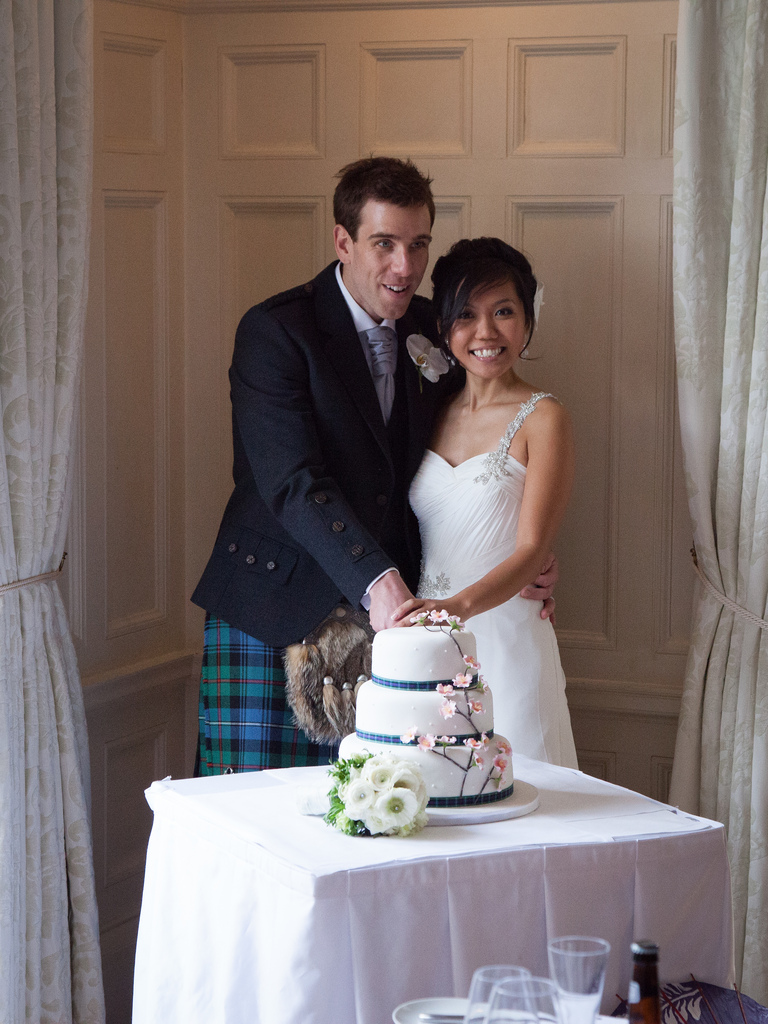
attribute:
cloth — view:
[119, 743, 758, 1022]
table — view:
[138, 746, 738, 1022]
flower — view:
[370, 779, 428, 832]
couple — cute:
[174, 140, 595, 779]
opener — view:
[624, 930, 668, 957]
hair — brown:
[322, 148, 444, 237]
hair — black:
[429, 231, 546, 317]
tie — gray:
[359, 323, 403, 415]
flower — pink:
[448, 669, 475, 691]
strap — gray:
[482, 384, 562, 456]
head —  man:
[338, 189, 431, 309]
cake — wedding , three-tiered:
[334, 624, 519, 797]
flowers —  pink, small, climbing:
[444, 636, 511, 796]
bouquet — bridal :
[328, 757, 435, 837]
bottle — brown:
[623, 943, 666, 1021]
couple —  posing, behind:
[204, 150, 583, 769]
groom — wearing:
[186, 164, 442, 772]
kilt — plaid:
[202, 611, 322, 764]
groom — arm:
[195, 161, 463, 739]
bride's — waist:
[406, 242, 574, 760]